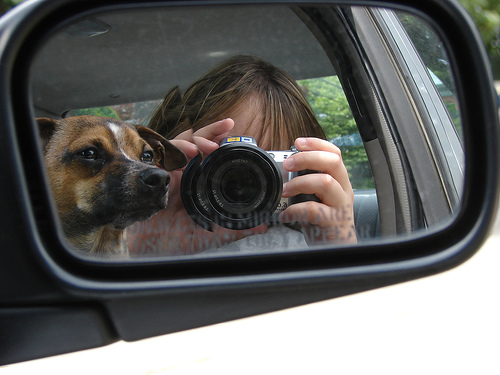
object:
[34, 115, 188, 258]
dog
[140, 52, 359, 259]
girl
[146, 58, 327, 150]
hair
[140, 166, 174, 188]
nose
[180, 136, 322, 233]
camera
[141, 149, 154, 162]
eye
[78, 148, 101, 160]
eye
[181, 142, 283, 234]
lens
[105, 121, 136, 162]
streak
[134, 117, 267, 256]
hand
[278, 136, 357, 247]
hand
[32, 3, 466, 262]
reflection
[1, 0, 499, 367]
mirror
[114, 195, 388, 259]
word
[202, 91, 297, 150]
forehead